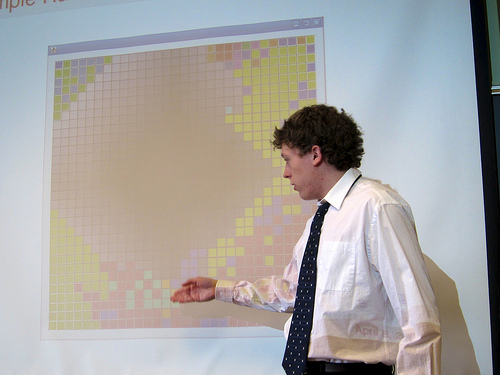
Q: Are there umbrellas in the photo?
A: No, there are no umbrellas.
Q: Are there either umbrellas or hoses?
A: No, there are no umbrellas or hoses.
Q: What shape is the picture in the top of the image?
A: The picture is square.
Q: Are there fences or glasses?
A: No, there are no glasses or fences.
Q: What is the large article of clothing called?
A: The clothing item is a shirt.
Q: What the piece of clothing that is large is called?
A: The clothing item is a shirt.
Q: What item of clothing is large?
A: The clothing item is a shirt.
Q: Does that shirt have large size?
A: Yes, the shirt is large.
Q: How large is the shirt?
A: The shirt is large.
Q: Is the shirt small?
A: No, the shirt is large.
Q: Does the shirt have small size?
A: No, the shirt is large.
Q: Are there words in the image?
A: Yes, there are words.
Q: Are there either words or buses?
A: Yes, there are words.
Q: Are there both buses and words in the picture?
A: No, there are words but no buses.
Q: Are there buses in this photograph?
A: No, there are no buses.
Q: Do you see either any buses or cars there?
A: No, there are no buses or cars.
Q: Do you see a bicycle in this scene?
A: No, there are no bicycles.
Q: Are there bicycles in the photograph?
A: No, there are no bicycles.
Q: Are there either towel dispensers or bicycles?
A: No, there are no bicycles or towel dispensers.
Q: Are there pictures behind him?
A: Yes, there is a picture behind the man.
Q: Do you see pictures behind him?
A: Yes, there is a picture behind the man.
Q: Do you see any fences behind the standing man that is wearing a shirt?
A: No, there is a picture behind the man.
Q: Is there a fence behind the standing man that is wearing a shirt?
A: No, there is a picture behind the man.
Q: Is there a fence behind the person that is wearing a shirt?
A: No, there is a picture behind the man.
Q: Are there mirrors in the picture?
A: No, there are no mirrors.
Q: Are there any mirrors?
A: No, there are no mirrors.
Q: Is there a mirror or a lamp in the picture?
A: No, there are no mirrors or lamps.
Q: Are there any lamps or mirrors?
A: No, there are no mirrors or lamps.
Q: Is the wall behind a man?
A: Yes, the wall is behind a man.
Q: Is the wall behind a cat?
A: No, the wall is behind a man.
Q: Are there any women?
A: No, there are no women.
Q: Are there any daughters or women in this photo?
A: No, there are no women or daughters.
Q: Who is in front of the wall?
A: The man is in front of the wall.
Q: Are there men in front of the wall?
A: Yes, there is a man in front of the wall.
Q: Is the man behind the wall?
A: No, the man is in front of the wall.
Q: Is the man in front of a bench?
A: No, the man is in front of the picture.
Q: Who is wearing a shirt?
A: The man is wearing a shirt.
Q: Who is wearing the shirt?
A: The man is wearing a shirt.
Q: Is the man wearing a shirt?
A: Yes, the man is wearing a shirt.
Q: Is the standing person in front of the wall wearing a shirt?
A: Yes, the man is wearing a shirt.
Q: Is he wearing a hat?
A: No, the man is wearing a shirt.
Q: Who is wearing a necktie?
A: The man is wearing a necktie.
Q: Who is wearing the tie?
A: The man is wearing a necktie.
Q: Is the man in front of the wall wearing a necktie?
A: Yes, the man is wearing a necktie.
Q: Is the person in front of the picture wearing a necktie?
A: Yes, the man is wearing a necktie.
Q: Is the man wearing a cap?
A: No, the man is wearing a necktie.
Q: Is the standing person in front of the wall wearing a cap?
A: No, the man is wearing a necktie.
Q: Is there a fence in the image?
A: No, there are no fences.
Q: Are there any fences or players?
A: No, there are no fences or players.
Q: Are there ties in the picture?
A: Yes, there is a tie.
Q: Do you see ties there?
A: Yes, there is a tie.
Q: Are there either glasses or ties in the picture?
A: Yes, there is a tie.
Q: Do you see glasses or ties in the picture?
A: Yes, there is a tie.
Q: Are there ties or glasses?
A: Yes, there is a tie.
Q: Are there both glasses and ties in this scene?
A: No, there is a tie but no glasses.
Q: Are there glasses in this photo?
A: No, there are no glasses.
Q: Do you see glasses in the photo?
A: No, there are no glasses.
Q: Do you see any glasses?
A: No, there are no glasses.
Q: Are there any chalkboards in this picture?
A: No, there are no chalkboards.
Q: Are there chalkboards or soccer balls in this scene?
A: No, there are no chalkboards or soccer balls.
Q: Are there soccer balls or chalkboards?
A: No, there are no chalkboards or soccer balls.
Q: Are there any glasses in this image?
A: No, there are no glasses.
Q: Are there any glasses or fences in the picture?
A: No, there are no glasses or fences.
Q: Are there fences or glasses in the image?
A: No, there are no glasses or fences.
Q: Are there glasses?
A: No, there are no glasses.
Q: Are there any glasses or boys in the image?
A: No, there are no glasses or boys.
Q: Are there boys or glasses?
A: No, there are no glasses or boys.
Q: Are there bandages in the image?
A: No, there are no bandages.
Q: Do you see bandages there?
A: No, there are no bandages.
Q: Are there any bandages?
A: No, there are no bandages.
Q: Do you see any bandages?
A: No, there are no bandages.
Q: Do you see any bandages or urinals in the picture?
A: No, there are no bandages or urinals.